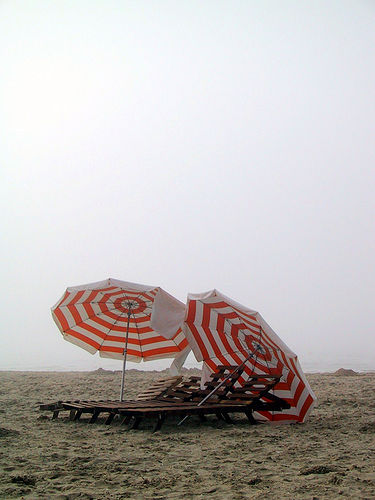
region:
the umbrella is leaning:
[259, 335, 316, 418]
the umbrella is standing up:
[91, 278, 149, 331]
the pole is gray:
[118, 360, 130, 388]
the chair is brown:
[134, 402, 184, 419]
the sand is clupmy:
[51, 440, 116, 494]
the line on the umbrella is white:
[88, 320, 105, 332]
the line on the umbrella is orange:
[76, 329, 90, 345]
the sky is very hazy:
[239, 215, 291, 263]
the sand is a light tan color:
[208, 451, 269, 486]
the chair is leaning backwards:
[245, 368, 277, 397]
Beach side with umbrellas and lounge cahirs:
[27, 208, 345, 454]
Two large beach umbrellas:
[30, 265, 330, 425]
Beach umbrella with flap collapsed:
[40, 259, 191, 365]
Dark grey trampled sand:
[0, 424, 373, 499]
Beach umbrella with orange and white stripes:
[186, 285, 316, 426]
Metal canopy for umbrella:
[97, 287, 153, 323]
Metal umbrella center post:
[116, 298, 134, 400]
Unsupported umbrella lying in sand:
[172, 281, 314, 428]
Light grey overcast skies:
[6, 111, 369, 273]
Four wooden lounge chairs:
[38, 355, 277, 434]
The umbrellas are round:
[51, 277, 188, 360]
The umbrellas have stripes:
[46, 283, 313, 424]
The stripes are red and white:
[40, 279, 314, 422]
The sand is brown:
[1, 426, 373, 499]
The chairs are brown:
[38, 364, 282, 426]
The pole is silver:
[120, 309, 132, 400]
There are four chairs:
[38, 365, 282, 428]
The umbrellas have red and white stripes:
[55, 275, 315, 422]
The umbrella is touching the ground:
[185, 293, 316, 425]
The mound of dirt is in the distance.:
[332, 368, 362, 378]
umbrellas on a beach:
[22, 163, 340, 495]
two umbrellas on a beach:
[19, 215, 313, 494]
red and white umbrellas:
[40, 225, 314, 497]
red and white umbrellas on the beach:
[63, 230, 361, 479]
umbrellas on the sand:
[73, 253, 291, 465]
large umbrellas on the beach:
[14, 210, 332, 493]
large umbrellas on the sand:
[40, 212, 292, 494]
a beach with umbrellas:
[49, 240, 347, 499]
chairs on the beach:
[40, 228, 308, 493]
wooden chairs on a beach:
[46, 312, 310, 498]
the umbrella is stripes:
[54, 272, 205, 401]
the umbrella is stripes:
[174, 290, 290, 437]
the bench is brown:
[38, 353, 261, 416]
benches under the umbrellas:
[27, 317, 279, 467]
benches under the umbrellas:
[40, 355, 273, 428]